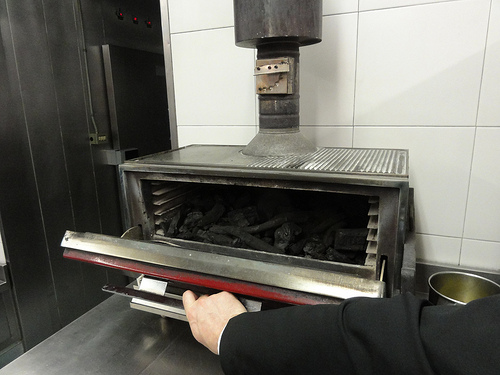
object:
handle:
[101, 279, 261, 325]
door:
[58, 217, 383, 323]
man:
[180, 285, 498, 374]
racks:
[365, 201, 377, 268]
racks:
[150, 185, 182, 227]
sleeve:
[217, 292, 497, 374]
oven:
[57, 142, 419, 336]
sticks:
[259, 191, 364, 253]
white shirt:
[217, 320, 229, 354]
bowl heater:
[60, 0, 414, 335]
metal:
[126, 328, 173, 370]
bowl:
[426, 270, 498, 304]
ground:
[118, 313, 158, 364]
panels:
[7, 9, 101, 208]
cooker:
[55, 227, 386, 337]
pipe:
[233, 2, 322, 157]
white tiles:
[170, 16, 482, 168]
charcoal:
[163, 197, 365, 273]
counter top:
[0, 278, 431, 373]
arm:
[216, 279, 500, 374]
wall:
[177, 10, 493, 173]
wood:
[166, 203, 256, 245]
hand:
[180, 287, 252, 363]